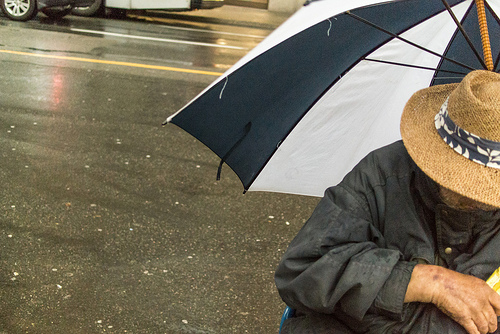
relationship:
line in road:
[0, 47, 223, 76] [1, 15, 498, 332]